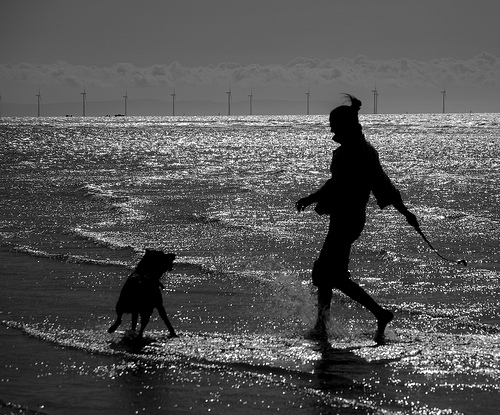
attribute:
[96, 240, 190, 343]
dog — wet, playing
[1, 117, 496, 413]
water — calm, wavy, rolling, splashing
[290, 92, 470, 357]
woman — kicking, playing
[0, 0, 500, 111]
sky — distant, cloudy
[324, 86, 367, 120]
hair — blowing